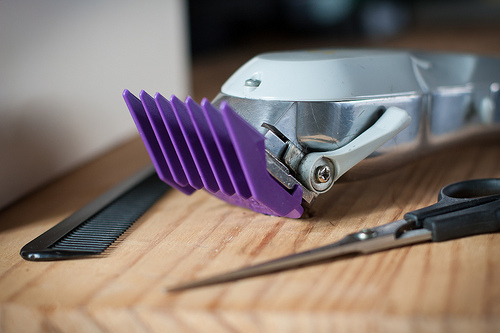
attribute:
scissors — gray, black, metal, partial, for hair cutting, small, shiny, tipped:
[175, 175, 499, 292]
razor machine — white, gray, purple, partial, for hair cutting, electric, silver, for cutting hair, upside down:
[122, 42, 500, 221]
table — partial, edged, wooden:
[2, 24, 499, 332]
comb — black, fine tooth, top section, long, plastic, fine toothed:
[19, 156, 171, 261]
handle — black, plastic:
[410, 177, 498, 242]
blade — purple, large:
[122, 86, 308, 220]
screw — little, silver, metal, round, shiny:
[358, 228, 373, 240]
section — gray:
[218, 47, 496, 193]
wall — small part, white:
[1, 2, 204, 235]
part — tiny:
[122, 86, 198, 196]